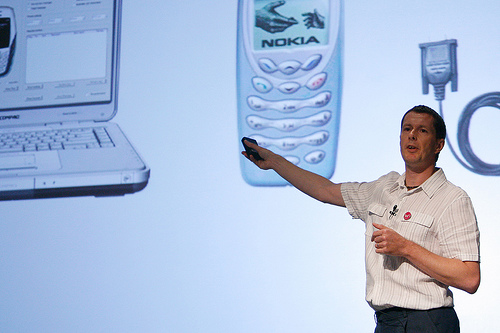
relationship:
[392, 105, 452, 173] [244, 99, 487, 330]
head of man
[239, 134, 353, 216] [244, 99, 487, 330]
arm of man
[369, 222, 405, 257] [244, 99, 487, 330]
hand of man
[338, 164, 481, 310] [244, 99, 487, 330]
shirt on man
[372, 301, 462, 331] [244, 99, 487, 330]
dress pants on man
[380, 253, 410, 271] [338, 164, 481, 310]
shadow casted on shirt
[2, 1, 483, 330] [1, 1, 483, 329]
image shown on background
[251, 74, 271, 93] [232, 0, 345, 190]
button built into cell phone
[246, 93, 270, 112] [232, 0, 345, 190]
button built into cell phone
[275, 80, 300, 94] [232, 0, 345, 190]
button built into cell phone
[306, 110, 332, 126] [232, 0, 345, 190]
button built into cell phone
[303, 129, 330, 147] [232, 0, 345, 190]
button built into cell phone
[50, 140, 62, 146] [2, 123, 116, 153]
key built into keyboard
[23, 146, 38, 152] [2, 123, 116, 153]
key built into keyboard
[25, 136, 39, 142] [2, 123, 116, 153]
key built into keyboard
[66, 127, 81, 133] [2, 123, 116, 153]
key built into keyboard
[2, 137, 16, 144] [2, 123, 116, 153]
key built into keyboard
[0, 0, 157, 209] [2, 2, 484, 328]
graphic shown in picture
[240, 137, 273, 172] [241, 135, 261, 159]
hand holding remote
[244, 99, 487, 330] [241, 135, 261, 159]
man holding remote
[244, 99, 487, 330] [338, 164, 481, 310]
man wearing shirt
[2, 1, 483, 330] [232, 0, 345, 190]
image showing cell phone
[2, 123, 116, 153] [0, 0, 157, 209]
keyboard built into graphic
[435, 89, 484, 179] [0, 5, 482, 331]
cable shown on wall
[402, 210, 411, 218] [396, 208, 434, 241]
button stuck on shirt pocket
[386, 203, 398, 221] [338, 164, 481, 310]
microphone clipped on shirt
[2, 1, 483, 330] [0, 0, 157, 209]
image showing graphic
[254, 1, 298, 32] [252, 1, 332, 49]
hand image shown on screen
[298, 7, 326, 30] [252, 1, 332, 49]
hand image shown on screen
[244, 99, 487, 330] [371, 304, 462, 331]
man wearing pants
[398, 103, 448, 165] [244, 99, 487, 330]
hair belonging to man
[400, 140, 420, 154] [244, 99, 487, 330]
mouth belonging to man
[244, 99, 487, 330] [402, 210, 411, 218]
man wearing button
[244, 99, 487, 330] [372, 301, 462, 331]
man wearing dress pants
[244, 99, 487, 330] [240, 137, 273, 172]
man pointing hand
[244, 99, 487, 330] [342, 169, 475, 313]
man wearing shirt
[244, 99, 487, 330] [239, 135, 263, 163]
man holding phone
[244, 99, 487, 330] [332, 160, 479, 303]
man wearing shirt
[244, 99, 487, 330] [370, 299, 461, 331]
man wearing pants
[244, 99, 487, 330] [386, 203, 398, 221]
man wearing microphone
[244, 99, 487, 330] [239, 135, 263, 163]
man using a phone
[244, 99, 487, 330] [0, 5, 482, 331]
man pointing at a wall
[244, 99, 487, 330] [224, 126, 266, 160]
man giving a speech with a projector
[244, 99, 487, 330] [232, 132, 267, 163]
man holding phone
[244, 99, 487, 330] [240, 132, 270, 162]
man holding phone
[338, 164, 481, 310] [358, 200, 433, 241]
shirt with pocket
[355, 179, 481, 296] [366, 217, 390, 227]
forearm with thumbs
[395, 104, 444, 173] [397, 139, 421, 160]
head with mouth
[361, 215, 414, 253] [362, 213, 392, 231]
hand with relaxed thumb